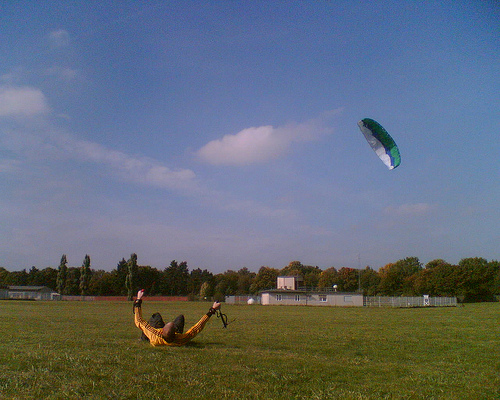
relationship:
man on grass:
[132, 290, 220, 347] [257, 312, 442, 377]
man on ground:
[132, 290, 220, 347] [75, 301, 272, 377]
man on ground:
[132, 287, 220, 347] [1, 290, 483, 396]